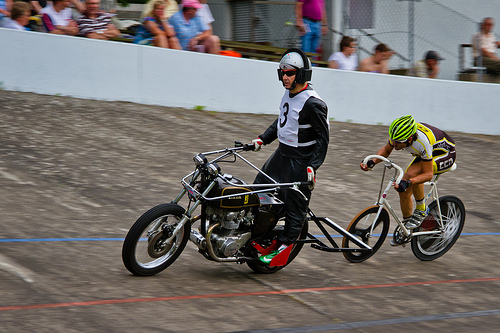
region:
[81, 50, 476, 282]
the pace car is a motorbike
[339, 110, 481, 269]
rider in an aerodynamic helmet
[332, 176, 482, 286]
a bike with tires of two sizes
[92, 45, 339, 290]
a bike with red stirrups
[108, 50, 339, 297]
a motorbike designed for standing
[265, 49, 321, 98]
a helmet with communications headphones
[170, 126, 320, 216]
a unique set of handlebars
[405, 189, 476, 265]
an unbalanced array of spokes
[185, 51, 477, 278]
two riders, one working hard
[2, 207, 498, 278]
two bikes below the blue line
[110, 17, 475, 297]
The man on the motorcycle is pulling the cyclist.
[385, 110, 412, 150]
The cyclist is wearing a neon colored helmet.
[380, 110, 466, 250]
The cyclist is wearing a spandex suit.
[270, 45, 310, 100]
The man on the motorcycle has a large helmet on.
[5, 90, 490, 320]
The men are on a track.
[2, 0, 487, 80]
There are people in the stands watching the two men.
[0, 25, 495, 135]
There is a barrier separating the track from the stands.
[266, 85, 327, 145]
The man on the motorcycle is wearing a bib.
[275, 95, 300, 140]
The bib has the number three written on it.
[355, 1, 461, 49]
A chain-link fence.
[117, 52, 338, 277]
a man on a motorbike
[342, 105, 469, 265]
a man on a bicycle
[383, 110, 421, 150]
green and black bicycle helmet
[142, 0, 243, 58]
audience for the riding event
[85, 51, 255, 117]
retaining wall for protection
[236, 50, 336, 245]
Uniformed official wearing a helmet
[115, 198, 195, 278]
front motorcycle tire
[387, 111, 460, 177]
bicycle riding clothing, shorts and top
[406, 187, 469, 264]
rear bicycle tire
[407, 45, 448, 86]
man in the audience wearing a hat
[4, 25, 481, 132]
white track sidewall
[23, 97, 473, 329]
mottled brown and white racetrack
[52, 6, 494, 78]
People sitting in stands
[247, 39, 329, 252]
Rider in black and white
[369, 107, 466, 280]
Cyclist in purple and yellow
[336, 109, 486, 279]
cyclist with green helmet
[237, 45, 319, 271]
Man with green shoes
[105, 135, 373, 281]
black and silver motorbike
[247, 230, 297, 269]
Red footrest on bike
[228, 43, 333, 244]
Man with white numbered jersey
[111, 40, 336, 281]
A man is riding a motorcycle.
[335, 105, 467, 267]
A person is riding a bicycle.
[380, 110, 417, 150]
A person is wearing a striped helmet.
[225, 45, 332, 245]
A man is wearing a black and white uniform.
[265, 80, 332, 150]
A man is wearing a vest with the number 3 on it.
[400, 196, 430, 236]
A person is wearing striped shoes.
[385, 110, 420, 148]
The color of this helmet is green and black.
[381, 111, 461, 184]
A person is wearing a white, yellow, and purple outfit.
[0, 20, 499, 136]
A white barrier is behind the riders.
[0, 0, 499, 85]
A group of people are in the stands.